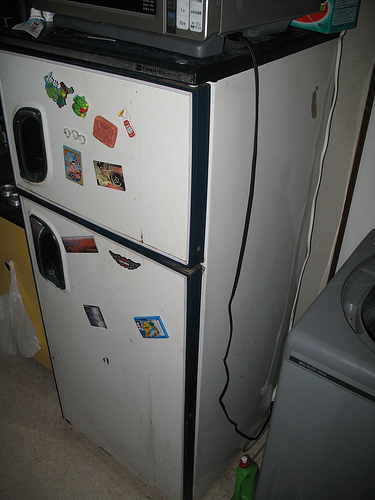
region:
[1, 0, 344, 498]
refrigerator with a microwave on top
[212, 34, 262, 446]
cord of microwave on side of fridge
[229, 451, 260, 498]
green detergent bottle on floor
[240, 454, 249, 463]
white pour cap on top green bottle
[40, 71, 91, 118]
green stickers on fridge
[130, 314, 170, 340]
blue sticker on fridge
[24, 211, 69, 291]
door handle on lower fridge door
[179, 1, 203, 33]
button menu on microwave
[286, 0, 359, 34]
soap box behind microwave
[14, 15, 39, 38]
empty toothpaste tube on top fridge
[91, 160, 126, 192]
a rectangular colorful magnet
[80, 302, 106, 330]
a rectangular colorful magnet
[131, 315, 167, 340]
a rectangular colorful magnet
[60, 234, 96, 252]
a rectangular colorful magnet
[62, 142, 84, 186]
a rectangular colorful magnet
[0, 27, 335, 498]
a small white refrigerator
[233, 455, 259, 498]
a green soap bottle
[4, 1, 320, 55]
a silver microwave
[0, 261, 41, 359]
a transparent white plastic bag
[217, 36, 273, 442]
a long black electrical cord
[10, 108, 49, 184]
a handle for a freezer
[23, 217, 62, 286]
a door handle for a refridgerator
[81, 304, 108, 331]
a magnet for a refridgerator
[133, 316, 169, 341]
a magnet for a refridgerator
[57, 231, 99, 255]
a magnet for a refridgerator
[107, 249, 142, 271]
a magnet for a refridgerator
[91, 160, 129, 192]
a magnet for a refridgerator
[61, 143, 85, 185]
a magnet for a refridgerator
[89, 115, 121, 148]
a magnet for a refridgerator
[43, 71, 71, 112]
a magnet for a refridgerator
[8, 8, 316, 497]
the refrigerator is made of metal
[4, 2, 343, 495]
the refrigerator is white in color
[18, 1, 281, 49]
a microwave is on top of the fridge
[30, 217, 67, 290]
a handle is on the refrigerator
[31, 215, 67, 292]
a handle is on the door of the refrigerator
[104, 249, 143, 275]
a decal is on the refrigerator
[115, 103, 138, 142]
a decal is on the refrigerator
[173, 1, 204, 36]
the controls are white in color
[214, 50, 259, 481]
a cord is hanging from the side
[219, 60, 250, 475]
the electrical cord is hanging from the side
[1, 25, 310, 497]
a white stacked refrigerator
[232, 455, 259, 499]
a green bottle with red and white spout cap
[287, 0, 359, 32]
a green cardboard box on top of fridge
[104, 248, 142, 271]
a winged magnet on fridge door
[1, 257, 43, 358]
a white plastic bag hanging on cabinet door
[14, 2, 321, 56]
a stainless steel and black microwave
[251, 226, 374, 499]
a grayish white washing machine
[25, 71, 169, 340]
decorative magnets on refrigerator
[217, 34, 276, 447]
a long black cord to microwave